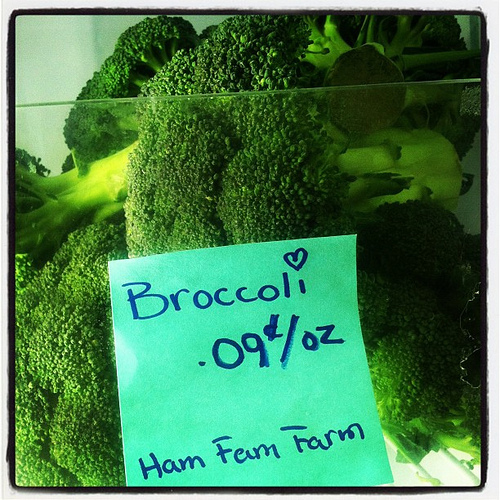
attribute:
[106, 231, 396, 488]
note — small, blue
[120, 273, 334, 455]
paper — blue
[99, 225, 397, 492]
sticky note — blue, clear, plastic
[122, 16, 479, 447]
broccoli — green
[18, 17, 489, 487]
broccoli — sold, raw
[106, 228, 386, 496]
paper — blue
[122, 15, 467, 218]
broccoli — dark, green, light, colors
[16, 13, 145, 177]
wall — white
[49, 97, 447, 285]
panel — clear